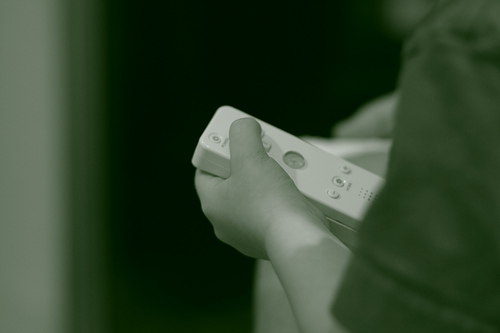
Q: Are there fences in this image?
A: No, there are no fences.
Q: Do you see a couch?
A: No, there are no couches.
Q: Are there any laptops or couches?
A: No, there are no couches or laptops.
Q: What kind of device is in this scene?
A: The device is a controller.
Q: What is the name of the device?
A: The device is a controller.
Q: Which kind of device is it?
A: The device is a controller.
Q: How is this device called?
A: This is a controller.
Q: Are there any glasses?
A: No, there are no glasses.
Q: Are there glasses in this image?
A: No, there are no glasses.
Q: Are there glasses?
A: No, there are no glasses.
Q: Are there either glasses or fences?
A: No, there are no glasses or fences.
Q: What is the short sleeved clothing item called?
A: The clothing item is a shirt.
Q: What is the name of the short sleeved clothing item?
A: The clothing item is a shirt.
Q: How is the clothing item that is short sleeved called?
A: The clothing item is a shirt.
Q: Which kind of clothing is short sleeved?
A: The clothing is a shirt.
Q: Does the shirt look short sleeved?
A: Yes, the shirt is short sleeved.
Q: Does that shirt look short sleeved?
A: Yes, the shirt is short sleeved.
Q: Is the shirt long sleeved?
A: No, the shirt is short sleeved.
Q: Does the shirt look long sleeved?
A: No, the shirt is short sleeved.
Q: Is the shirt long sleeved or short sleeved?
A: The shirt is short sleeved.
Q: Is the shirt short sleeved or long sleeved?
A: The shirt is short sleeved.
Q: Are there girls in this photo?
A: No, there are no girls.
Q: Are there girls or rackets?
A: No, there are no girls or rackets.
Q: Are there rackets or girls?
A: No, there are no girls or rackets.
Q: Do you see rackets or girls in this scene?
A: No, there are no girls or rackets.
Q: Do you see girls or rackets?
A: No, there are no girls or rackets.